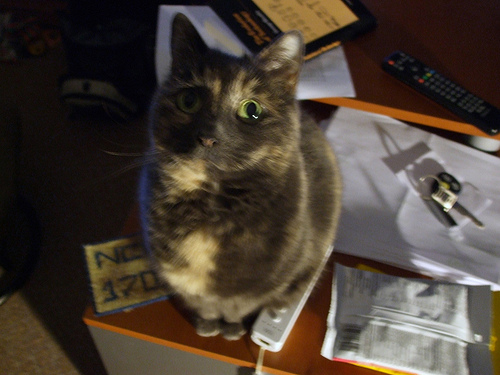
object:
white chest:
[161, 229, 217, 293]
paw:
[220, 321, 249, 342]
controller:
[249, 240, 333, 352]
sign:
[83, 235, 171, 313]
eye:
[237, 99, 262, 122]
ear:
[253, 31, 304, 89]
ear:
[170, 13, 204, 63]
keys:
[429, 171, 485, 229]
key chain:
[417, 174, 442, 199]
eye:
[177, 86, 202, 113]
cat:
[145, 30, 340, 341]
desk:
[83, 3, 500, 375]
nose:
[194, 132, 219, 149]